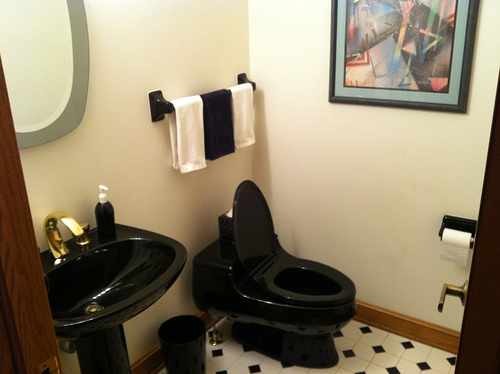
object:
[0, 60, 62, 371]
door jamb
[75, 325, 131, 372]
sink base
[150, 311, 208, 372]
trash can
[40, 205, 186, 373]
sink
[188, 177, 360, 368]
toilet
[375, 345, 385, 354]
diamond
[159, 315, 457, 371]
floor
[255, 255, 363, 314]
toilet seat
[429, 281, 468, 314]
handle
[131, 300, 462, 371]
base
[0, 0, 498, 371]
wall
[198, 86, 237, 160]
towel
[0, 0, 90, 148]
mirror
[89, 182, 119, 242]
soap dispenser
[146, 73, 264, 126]
towel rack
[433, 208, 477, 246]
toilet paper rack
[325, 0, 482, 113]
artwork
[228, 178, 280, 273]
lid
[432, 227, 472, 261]
toilet paper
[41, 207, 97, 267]
faucet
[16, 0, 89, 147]
silver frame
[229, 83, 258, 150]
towel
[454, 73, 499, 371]
door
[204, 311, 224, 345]
water pipe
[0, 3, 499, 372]
bathroom